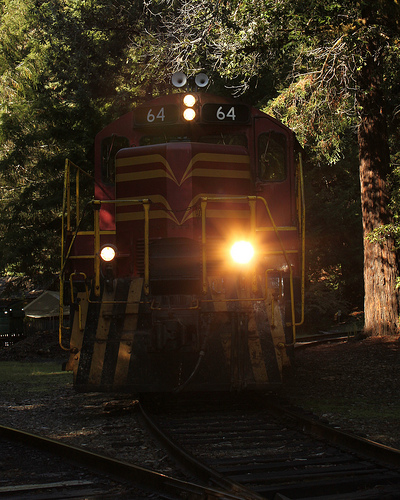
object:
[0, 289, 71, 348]
building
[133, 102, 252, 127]
en-printed numbers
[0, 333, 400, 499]
ground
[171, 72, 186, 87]
horn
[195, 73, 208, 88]
horn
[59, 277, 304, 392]
bumper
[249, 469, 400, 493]
plank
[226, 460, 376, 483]
plank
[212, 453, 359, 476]
plank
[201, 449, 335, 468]
plank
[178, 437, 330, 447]
plank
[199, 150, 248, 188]
wall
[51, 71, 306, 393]
train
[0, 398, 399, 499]
track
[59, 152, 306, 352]
hand rail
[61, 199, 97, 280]
steps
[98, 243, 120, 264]
head lights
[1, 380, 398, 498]
railings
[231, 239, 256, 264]
headlight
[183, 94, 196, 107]
headlight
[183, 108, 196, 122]
headlight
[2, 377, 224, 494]
gravel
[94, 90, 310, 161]
tops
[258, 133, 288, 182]
windshield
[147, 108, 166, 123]
number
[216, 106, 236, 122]
number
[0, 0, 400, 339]
tree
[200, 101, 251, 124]
black